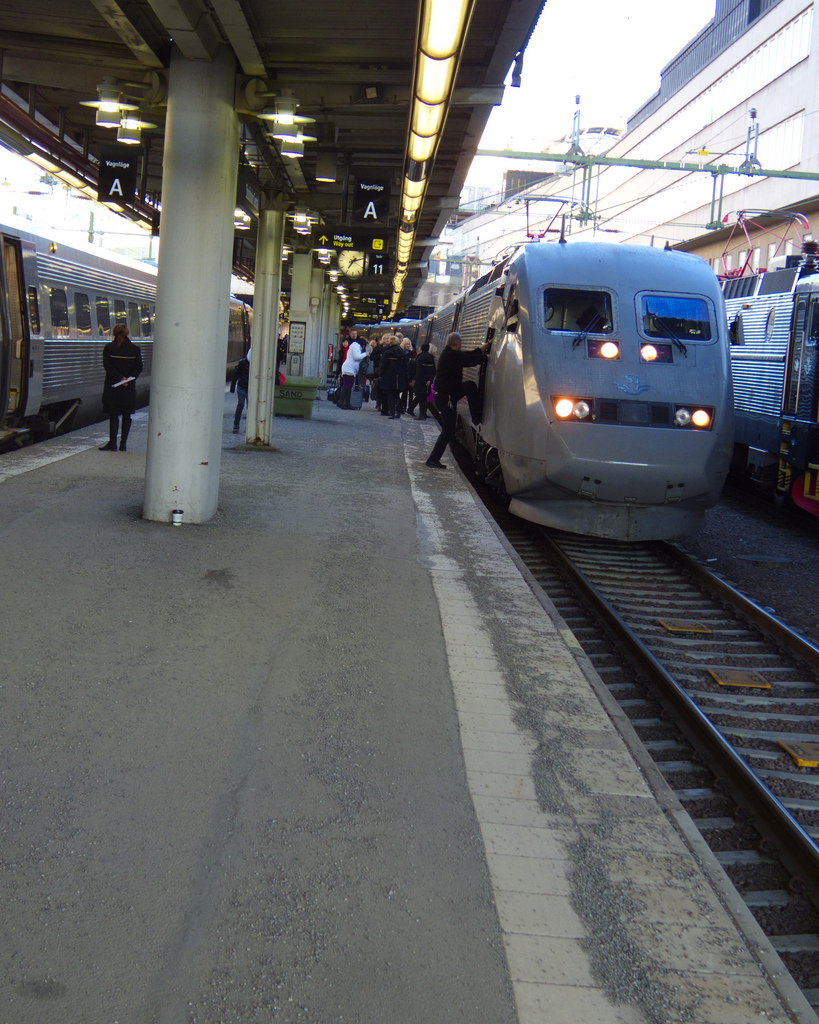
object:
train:
[0, 216, 363, 467]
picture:
[0, 0, 819, 763]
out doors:
[491, 47, 751, 742]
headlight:
[592, 331, 626, 369]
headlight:
[636, 337, 664, 368]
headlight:
[552, 394, 577, 420]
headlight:
[573, 395, 593, 422]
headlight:
[669, 401, 695, 429]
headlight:
[689, 404, 716, 431]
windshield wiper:
[571, 290, 622, 363]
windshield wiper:
[631, 302, 693, 357]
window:
[625, 264, 723, 357]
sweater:
[341, 342, 370, 375]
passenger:
[334, 333, 373, 416]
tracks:
[525, 532, 775, 558]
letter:
[358, 180, 392, 227]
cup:
[165, 495, 187, 539]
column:
[123, 56, 247, 533]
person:
[90, 314, 150, 467]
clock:
[328, 237, 375, 289]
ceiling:
[0, 0, 547, 328]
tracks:
[654, 649, 817, 673]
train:
[345, 225, 758, 576]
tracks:
[603, 700, 819, 723]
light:
[389, 162, 429, 218]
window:
[38, 277, 78, 336]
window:
[538, 267, 619, 344]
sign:
[340, 164, 395, 239]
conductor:
[409, 314, 493, 475]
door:
[462, 263, 526, 451]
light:
[394, 2, 484, 53]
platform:
[0, 285, 802, 1022]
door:
[0, 225, 36, 432]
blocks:
[655, 654, 817, 674]